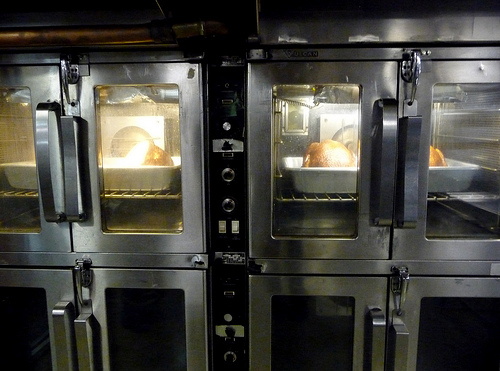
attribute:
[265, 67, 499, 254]
window — glass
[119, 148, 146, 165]
light — on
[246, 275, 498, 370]
oven — large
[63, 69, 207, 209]
light — shining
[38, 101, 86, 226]
handles — silver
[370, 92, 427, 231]
handles — silver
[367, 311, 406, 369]
handles — silver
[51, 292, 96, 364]
handles — silver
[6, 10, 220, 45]
pipe — copper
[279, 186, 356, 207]
grate — metal, grey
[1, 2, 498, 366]
commercial ovens — large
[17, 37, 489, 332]
ovens — large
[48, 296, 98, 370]
handles — silver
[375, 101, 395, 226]
handle — metal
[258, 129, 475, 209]
pan — grey, metal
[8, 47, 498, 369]
doors — silver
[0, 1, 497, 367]
ovens — large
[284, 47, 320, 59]
sticker — black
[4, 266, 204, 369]
oven — large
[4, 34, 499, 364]
ovens — large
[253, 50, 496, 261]
doors — silver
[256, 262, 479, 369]
doors — silver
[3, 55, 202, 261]
doors — silver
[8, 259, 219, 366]
doors — silver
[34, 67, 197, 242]
oven — large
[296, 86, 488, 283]
oven — large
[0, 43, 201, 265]
oven — large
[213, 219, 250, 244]
switch — white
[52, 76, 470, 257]
ovens — large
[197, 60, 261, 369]
panel — vertical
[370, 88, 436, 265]
handles — silver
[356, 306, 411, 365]
handles — silver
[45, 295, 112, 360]
handles — silver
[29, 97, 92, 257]
handles — silver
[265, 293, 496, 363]
glass — blackened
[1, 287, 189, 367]
glass — blackened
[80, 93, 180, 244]
light — shining